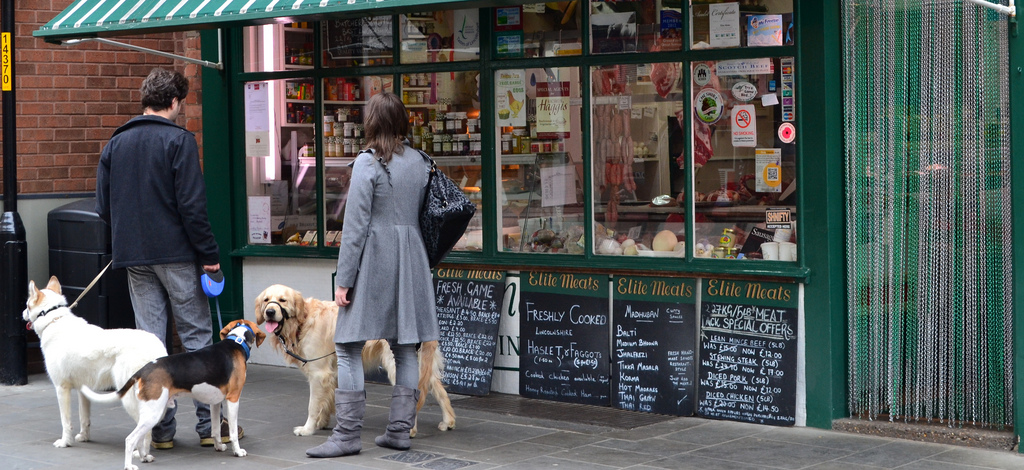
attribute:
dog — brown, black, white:
[81, 311, 271, 467]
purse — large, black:
[417, 148, 472, 269]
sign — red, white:
[728, 101, 757, 146]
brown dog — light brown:
[241, 277, 407, 443]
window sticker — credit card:
[774, 54, 801, 127]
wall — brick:
[15, 13, 199, 197]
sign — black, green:
[513, 253, 624, 412]